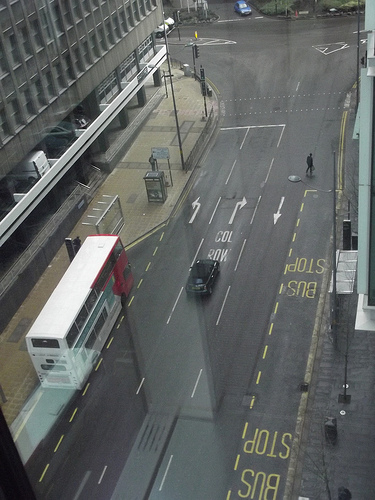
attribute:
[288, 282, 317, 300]
word — bus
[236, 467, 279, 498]
word — bus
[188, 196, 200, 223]
arrow — white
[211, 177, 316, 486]
lines — yellow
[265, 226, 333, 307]
words — golden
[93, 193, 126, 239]
bus stop — metal and glass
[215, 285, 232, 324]
markings — white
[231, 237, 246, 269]
markings — white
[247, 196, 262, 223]
markings — white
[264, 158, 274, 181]
markings — white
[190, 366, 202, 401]
markings — white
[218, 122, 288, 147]
marking — white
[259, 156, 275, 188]
marking — white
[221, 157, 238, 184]
marking — white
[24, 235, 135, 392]
bus — parked, double decker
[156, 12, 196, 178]
street light — metal